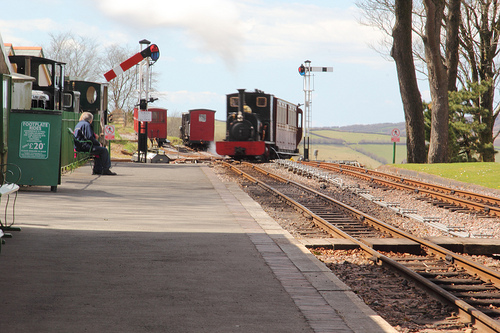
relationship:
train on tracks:
[219, 89, 304, 164] [215, 154, 500, 332]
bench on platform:
[65, 127, 112, 171] [0, 160, 398, 331]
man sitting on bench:
[74, 112, 113, 176] [65, 127, 112, 171]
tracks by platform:
[215, 154, 500, 332] [0, 160, 398, 331]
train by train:
[219, 89, 304, 164] [180, 107, 215, 149]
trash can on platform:
[7, 106, 63, 189] [0, 160, 398, 331]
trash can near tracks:
[7, 106, 63, 189] [215, 154, 500, 332]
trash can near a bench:
[7, 106, 63, 189] [1, 147, 22, 241]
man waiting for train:
[74, 112, 113, 176] [219, 89, 304, 164]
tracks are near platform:
[215, 154, 500, 332] [0, 160, 398, 331]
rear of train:
[189, 109, 215, 143] [180, 107, 215, 149]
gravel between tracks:
[218, 156, 499, 332] [215, 154, 500, 332]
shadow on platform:
[2, 227, 385, 331] [0, 160, 398, 331]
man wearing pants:
[74, 112, 113, 176] [84, 145, 113, 167]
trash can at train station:
[7, 106, 63, 189] [0, 53, 396, 331]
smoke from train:
[109, 10, 246, 87] [219, 89, 304, 164]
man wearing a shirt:
[74, 112, 113, 176] [73, 121, 90, 141]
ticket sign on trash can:
[18, 120, 49, 158] [7, 106, 63, 189]